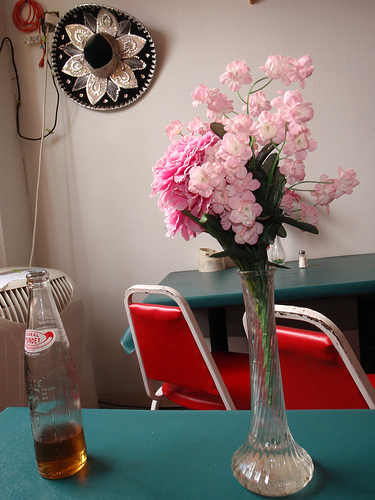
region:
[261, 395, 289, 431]
part of a glass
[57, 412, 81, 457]
part of a leve;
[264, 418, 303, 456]
part of a glass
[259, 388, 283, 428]
part of a liune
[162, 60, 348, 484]
pink flowers in a vase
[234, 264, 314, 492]
glass vase with water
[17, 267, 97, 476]
half empty cola bottle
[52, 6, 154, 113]
mexican flower hat on wall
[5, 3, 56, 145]
electric wire hanging on wall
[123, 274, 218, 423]
old red chair at table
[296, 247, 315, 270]
salt shaker on table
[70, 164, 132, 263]
white painted wall in room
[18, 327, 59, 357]
cola lable on bottle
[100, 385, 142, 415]
black cord along the wall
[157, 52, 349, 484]
This is a flower vase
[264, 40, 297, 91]
This is a flower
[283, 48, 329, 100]
This is a flower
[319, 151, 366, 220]
This is a flower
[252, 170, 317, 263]
This is a flower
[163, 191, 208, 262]
This is a flower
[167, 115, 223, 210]
This is a flowerThis is a flower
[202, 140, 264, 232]
This is a flower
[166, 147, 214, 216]
This is a flower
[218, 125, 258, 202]
This is a flower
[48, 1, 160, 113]
A black and white sombrero.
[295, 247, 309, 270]
A salt shaker on a table.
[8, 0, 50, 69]
A orange cord on the wall.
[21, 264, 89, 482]
A glass bottle on the table.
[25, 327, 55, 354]
A red and white label.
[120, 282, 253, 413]
A red and white chair.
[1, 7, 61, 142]
A black cord on the wall.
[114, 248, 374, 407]
A blue table on the wall.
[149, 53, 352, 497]
Pink flowers in a vase.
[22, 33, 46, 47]
A tag on a cord.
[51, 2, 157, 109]
black and white hat hanging on wall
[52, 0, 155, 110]
large hat in the background of photo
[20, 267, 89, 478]
glass bottle of soda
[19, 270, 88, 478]
almost completely finished bottle of soda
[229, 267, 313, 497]
glass vase on table with water in it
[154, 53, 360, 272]
pink flowers arranged in clear vase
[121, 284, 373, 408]
red chairs with plastic covering cushions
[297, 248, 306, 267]
salt shaker on table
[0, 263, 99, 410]
air conditioner/ heater in corner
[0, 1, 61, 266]
wires hanging on wall